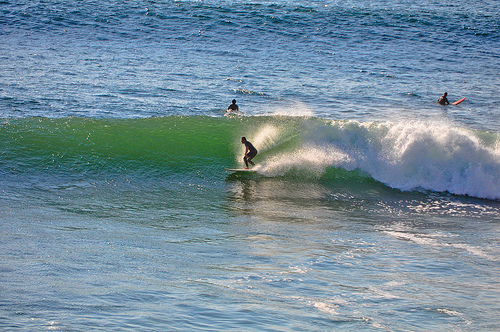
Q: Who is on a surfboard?
A: A man.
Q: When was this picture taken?
A: During the day.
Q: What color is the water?
A: Blue.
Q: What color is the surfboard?
A: White.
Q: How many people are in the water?
A: Three.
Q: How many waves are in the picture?
A: One.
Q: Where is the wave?
A: In the ocean.